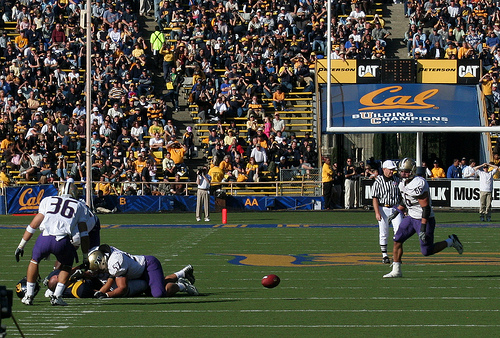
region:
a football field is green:
[159, 193, 350, 333]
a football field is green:
[182, 121, 321, 308]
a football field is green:
[110, 106, 475, 311]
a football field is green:
[224, 214, 326, 327]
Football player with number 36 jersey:
[9, 172, 106, 314]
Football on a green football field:
[231, 239, 298, 313]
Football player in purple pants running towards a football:
[219, 132, 471, 309]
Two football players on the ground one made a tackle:
[26, 218, 212, 314]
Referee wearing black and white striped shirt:
[360, 147, 411, 271]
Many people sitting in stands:
[103, 6, 315, 177]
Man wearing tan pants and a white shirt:
[189, 162, 223, 226]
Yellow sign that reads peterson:
[412, 50, 467, 94]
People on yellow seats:
[180, 59, 319, 164]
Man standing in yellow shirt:
[164, 131, 194, 166]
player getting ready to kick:
[353, 146, 470, 290]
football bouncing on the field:
[253, 265, 293, 300]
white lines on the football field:
[326, 277, 436, 330]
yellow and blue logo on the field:
[206, 241, 371, 266]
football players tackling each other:
[12, 170, 220, 323]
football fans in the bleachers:
[28, 87, 304, 164]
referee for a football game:
[363, 156, 403, 260]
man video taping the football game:
[194, 162, 215, 225]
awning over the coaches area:
[317, 86, 486, 131]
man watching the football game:
[465, 157, 497, 225]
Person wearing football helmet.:
[393, 147, 421, 197]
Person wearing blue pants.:
[402, 213, 427, 235]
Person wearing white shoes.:
[369, 250, 433, 306]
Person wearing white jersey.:
[395, 183, 439, 211]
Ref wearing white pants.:
[369, 226, 387, 232]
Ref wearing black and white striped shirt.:
[363, 170, 411, 212]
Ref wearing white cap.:
[380, 153, 397, 171]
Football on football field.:
[252, 265, 315, 305]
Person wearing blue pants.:
[142, 255, 182, 303]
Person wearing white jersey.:
[109, 247, 163, 299]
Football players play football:
[15, 170, 199, 332]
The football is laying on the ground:
[242, 232, 287, 309]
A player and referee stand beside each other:
[364, 152, 482, 294]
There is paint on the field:
[215, 243, 372, 283]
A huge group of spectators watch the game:
[114, 5, 387, 168]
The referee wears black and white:
[365, 163, 410, 282]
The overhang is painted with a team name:
[323, 70, 483, 135]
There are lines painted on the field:
[302, 272, 339, 326]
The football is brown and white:
[245, 268, 290, 305]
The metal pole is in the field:
[80, 1, 127, 209]